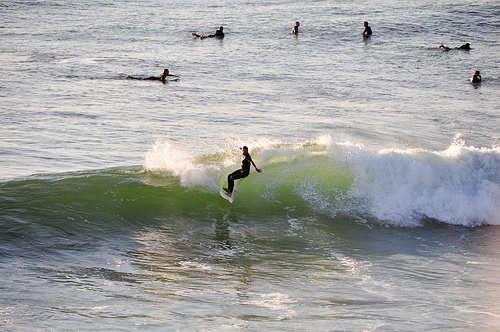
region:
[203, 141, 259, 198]
man is on surfboard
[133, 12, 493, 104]
people are in water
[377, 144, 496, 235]
white wave is crashing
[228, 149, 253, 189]
man has black wetsuit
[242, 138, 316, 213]
water is bluish green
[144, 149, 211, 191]
man creates white wake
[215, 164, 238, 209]
man on white board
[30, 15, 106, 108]
calm water behind wave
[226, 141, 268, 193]
man has arms extended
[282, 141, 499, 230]
one large white wave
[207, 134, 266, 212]
person surfing on ocean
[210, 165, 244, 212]
white surfboard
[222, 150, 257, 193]
black wet suit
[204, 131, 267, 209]
person riding a wave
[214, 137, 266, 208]
person standing on surfboard with bent knees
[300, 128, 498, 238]
large white wave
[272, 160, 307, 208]
green tinted water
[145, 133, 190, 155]
water splash in air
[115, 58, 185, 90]
person in water on surfboard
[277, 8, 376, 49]
people swimming in ocean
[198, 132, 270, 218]
person surfing in ocean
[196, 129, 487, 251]
large water wave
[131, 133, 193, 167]
white water splash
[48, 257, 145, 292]
dark ripples in water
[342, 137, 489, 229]
white water wave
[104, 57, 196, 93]
person lying on surfboard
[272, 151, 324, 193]
green tinted ocean water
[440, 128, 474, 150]
white water splash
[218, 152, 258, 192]
black wetsuit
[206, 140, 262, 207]
A man on a surfboard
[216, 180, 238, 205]
A white surfboard on a wave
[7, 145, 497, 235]
A wave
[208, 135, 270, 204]
A man surfing a wave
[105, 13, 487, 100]
A group of people in the water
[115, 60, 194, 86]
Person laying on a surfboard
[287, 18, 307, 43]
Person standing in the water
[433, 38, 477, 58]
Person floating in the water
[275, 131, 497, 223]
The spray of a wave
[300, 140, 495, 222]
White spray of a wave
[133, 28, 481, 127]
people in the ocean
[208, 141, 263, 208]
the man in the ocean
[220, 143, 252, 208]
the man on the surfboard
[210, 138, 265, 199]
the man is surfing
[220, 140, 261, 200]
the man wearing wetsuit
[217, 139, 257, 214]
the man is wet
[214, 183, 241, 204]
the surfboard is white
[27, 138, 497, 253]
the wave in the ocean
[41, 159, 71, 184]
the crest of teh wave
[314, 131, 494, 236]
the wave is splashing